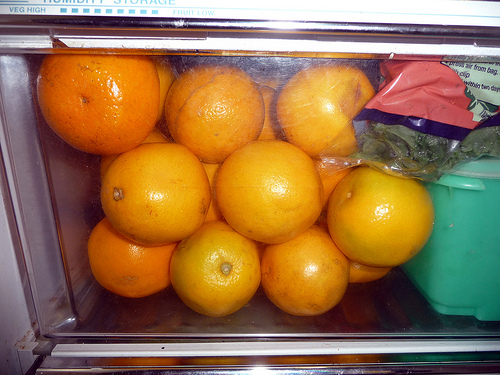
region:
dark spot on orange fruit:
[68, 87, 94, 117]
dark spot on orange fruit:
[76, 89, 96, 111]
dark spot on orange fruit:
[71, 79, 99, 126]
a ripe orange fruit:
[32, 53, 157, 153]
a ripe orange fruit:
[95, 145, 212, 241]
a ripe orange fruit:
[85, 219, 169, 297]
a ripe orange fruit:
[168, 227, 260, 315]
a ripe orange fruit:
[268, 231, 345, 316]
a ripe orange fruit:
[211, 139, 316, 246]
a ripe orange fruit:
[325, 171, 432, 269]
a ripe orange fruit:
[274, 66, 367, 153]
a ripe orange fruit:
[348, 259, 391, 283]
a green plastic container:
[420, 148, 498, 321]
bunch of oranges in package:
[51, 27, 411, 317]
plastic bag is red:
[370, 76, 490, 135]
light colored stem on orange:
[211, 261, 226, 282]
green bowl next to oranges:
[377, 151, 499, 328]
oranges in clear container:
[35, 53, 453, 323]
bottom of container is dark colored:
[96, 278, 429, 350]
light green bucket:
[412, 155, 499, 302]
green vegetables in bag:
[365, 116, 461, 183]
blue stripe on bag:
[321, 91, 471, 140]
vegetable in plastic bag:
[363, 96, 459, 182]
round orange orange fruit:
[168, 227, 266, 324]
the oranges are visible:
[100, 84, 280, 365]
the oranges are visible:
[180, 193, 281, 265]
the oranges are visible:
[127, 149, 326, 337]